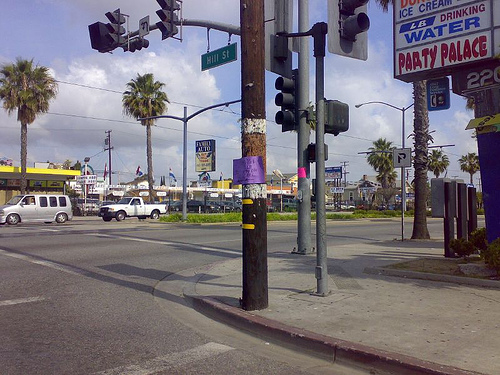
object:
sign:
[201, 42, 238, 72]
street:
[0, 213, 499, 372]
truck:
[98, 194, 170, 223]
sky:
[0, 0, 483, 191]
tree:
[2, 55, 56, 192]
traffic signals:
[86, 3, 127, 55]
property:
[170, 176, 226, 204]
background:
[0, 1, 499, 375]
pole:
[176, 105, 191, 219]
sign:
[194, 139, 216, 174]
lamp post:
[134, 111, 181, 124]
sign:
[391, 147, 413, 168]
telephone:
[428, 178, 453, 220]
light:
[271, 73, 296, 92]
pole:
[239, 0, 269, 311]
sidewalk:
[195, 238, 498, 372]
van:
[0, 193, 74, 225]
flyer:
[229, 155, 261, 186]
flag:
[167, 170, 175, 182]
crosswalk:
[15, 218, 212, 283]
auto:
[195, 146, 213, 152]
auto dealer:
[165, 183, 295, 216]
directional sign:
[138, 12, 151, 38]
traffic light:
[155, 0, 173, 39]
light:
[273, 111, 291, 127]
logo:
[393, 31, 491, 81]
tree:
[121, 71, 165, 204]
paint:
[240, 118, 265, 135]